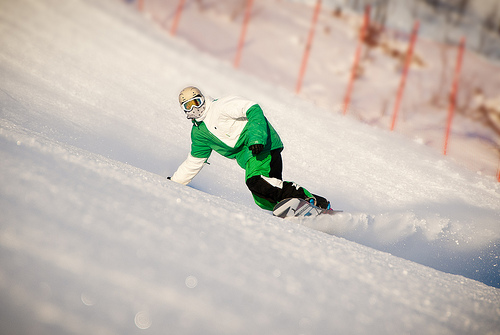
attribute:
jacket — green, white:
[171, 98, 283, 185]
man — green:
[166, 81, 333, 220]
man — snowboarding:
[141, 30, 346, 228]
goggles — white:
[177, 98, 207, 111]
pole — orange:
[230, 0, 260, 82]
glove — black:
[230, 141, 275, 166]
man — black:
[149, 54, 374, 228]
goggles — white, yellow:
[181, 94, 204, 111]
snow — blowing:
[0, 1, 497, 332]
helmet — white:
[177, 84, 205, 121]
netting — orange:
[283, 10, 452, 123]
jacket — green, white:
[208, 95, 273, 167]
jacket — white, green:
[159, 75, 296, 190]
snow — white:
[83, 140, 441, 330]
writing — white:
[281, 202, 320, 218]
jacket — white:
[147, 109, 277, 169]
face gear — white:
[164, 74, 204, 118]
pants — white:
[241, 170, 346, 237]